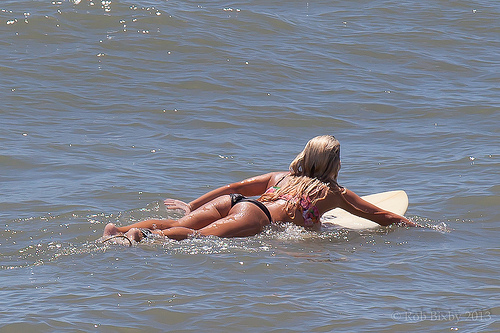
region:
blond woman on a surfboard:
[91, 128, 430, 252]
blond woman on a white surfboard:
[77, 133, 422, 278]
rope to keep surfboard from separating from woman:
[95, 229, 134, 254]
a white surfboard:
[260, 181, 421, 246]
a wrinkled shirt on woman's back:
[263, 172, 336, 219]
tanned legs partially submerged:
[94, 190, 261, 255]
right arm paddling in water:
[340, 187, 440, 239]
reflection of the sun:
[96, 0, 113, 17]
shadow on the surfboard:
[287, 217, 349, 237]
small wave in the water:
[243, 102, 354, 134]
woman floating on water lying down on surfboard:
[102, 133, 422, 251]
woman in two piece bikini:
[102, 134, 424, 254]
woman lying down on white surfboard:
[101, 133, 418, 249]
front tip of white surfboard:
[321, 184, 408, 230]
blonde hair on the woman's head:
[270, 134, 340, 221]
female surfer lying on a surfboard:
[96, 135, 450, 253]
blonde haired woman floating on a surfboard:
[14, 57, 488, 319]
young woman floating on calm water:
[1, 60, 498, 330]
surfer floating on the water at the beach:
[0, 0, 496, 330]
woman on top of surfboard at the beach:
[100, 133, 440, 250]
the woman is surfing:
[45, 37, 486, 308]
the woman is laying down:
[57, 75, 471, 279]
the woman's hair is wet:
[267, 94, 415, 248]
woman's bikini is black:
[170, 157, 292, 258]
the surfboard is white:
[284, 157, 446, 248]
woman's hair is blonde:
[250, 82, 382, 217]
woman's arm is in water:
[315, 176, 435, 233]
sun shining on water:
[1, 0, 249, 68]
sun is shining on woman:
[53, 49, 418, 279]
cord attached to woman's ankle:
[118, 226, 168, 260]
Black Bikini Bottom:
[226, 188, 273, 222]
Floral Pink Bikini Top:
[265, 172, 332, 234]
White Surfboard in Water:
[310, 186, 413, 229]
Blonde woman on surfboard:
[99, 128, 414, 257]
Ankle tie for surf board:
[98, 225, 162, 256]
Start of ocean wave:
[2, 3, 299, 77]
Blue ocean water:
[3, 43, 455, 130]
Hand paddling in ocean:
[146, 191, 196, 219]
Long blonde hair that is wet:
[287, 128, 342, 211]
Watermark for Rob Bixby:
[383, 302, 493, 322]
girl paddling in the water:
[182, 120, 403, 266]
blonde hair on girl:
[280, 125, 355, 202]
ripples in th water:
[150, 260, 235, 321]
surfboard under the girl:
[380, 176, 415, 216]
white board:
[371, 176, 411, 221]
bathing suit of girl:
[200, 171, 332, 241]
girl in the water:
[171, 120, 356, 285]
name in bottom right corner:
[383, 290, 486, 332]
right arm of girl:
[373, 190, 446, 249]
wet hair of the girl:
[291, 136, 348, 184]